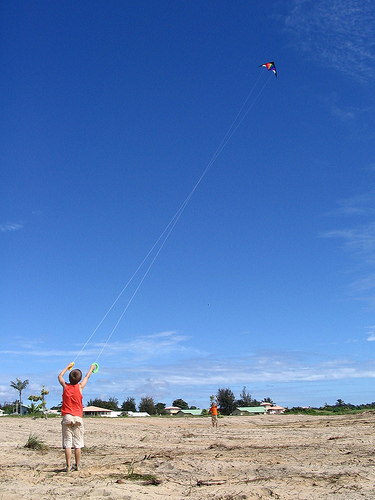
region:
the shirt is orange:
[59, 384, 84, 416]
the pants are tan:
[59, 414, 88, 449]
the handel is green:
[92, 360, 103, 373]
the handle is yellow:
[67, 359, 77, 370]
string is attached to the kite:
[140, 178, 213, 244]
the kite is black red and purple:
[256, 59, 282, 76]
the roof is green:
[241, 403, 266, 412]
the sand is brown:
[185, 440, 303, 496]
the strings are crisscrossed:
[175, 157, 223, 216]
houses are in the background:
[90, 393, 290, 425]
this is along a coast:
[40, 51, 303, 430]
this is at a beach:
[16, 76, 336, 474]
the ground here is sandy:
[117, 447, 308, 494]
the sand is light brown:
[166, 435, 313, 492]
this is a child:
[31, 353, 125, 462]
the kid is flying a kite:
[59, 367, 128, 444]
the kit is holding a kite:
[45, 347, 125, 497]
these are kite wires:
[47, 101, 260, 303]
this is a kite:
[233, 46, 318, 105]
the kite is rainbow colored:
[243, 62, 307, 90]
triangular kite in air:
[260, 58, 279, 77]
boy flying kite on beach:
[56, 356, 103, 474]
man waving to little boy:
[206, 392, 223, 428]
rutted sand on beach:
[0, 414, 374, 498]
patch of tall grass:
[24, 429, 50, 452]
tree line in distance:
[1, 373, 373, 414]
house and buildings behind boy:
[79, 401, 148, 418]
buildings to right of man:
[234, 397, 284, 417]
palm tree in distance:
[10, 375, 28, 413]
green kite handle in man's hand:
[87, 360, 99, 375]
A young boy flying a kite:
[39, 50, 283, 478]